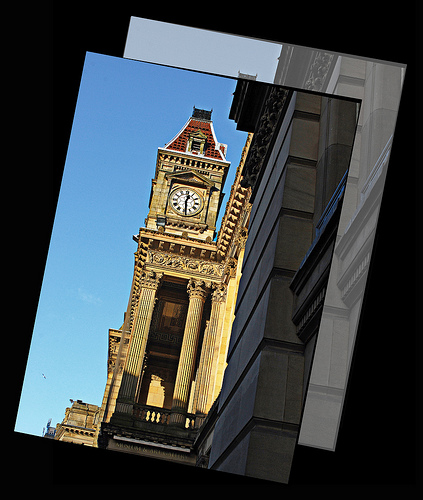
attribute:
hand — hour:
[185, 193, 191, 213]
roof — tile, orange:
[159, 103, 230, 168]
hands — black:
[180, 191, 198, 213]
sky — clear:
[15, 49, 245, 436]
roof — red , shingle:
[163, 120, 222, 165]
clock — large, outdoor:
[168, 183, 205, 219]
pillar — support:
[107, 271, 157, 426]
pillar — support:
[170, 276, 208, 432]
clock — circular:
[166, 178, 208, 218]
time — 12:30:
[172, 189, 200, 214]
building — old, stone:
[131, 116, 218, 383]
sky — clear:
[23, 54, 187, 454]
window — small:
[182, 131, 221, 160]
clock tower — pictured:
[130, 91, 237, 245]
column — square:
[109, 267, 164, 430]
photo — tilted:
[19, 47, 373, 348]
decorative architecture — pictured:
[132, 87, 289, 280]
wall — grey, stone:
[201, 91, 319, 498]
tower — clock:
[101, 94, 230, 438]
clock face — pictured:
[174, 189, 201, 217]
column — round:
[160, 274, 211, 433]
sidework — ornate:
[133, 244, 219, 281]